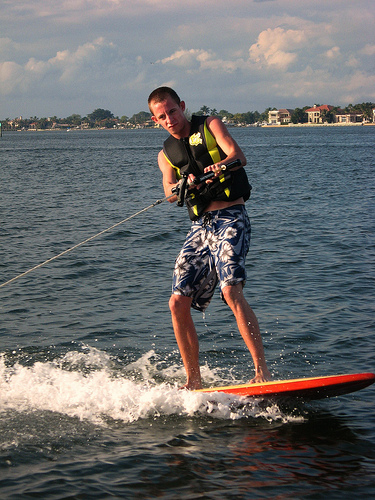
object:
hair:
[148, 86, 181, 115]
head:
[148, 86, 185, 134]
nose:
[165, 112, 173, 124]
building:
[335, 110, 365, 123]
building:
[305, 104, 341, 123]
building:
[268, 109, 293, 125]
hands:
[204, 161, 221, 183]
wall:
[268, 111, 277, 123]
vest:
[162, 114, 251, 220]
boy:
[148, 87, 272, 392]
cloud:
[0, 0, 375, 110]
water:
[268, 148, 358, 331]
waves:
[0, 346, 284, 426]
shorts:
[171, 203, 251, 312]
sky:
[0, 0, 375, 103]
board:
[191, 371, 375, 396]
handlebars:
[171, 158, 242, 193]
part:
[289, 372, 375, 399]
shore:
[0, 119, 375, 133]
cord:
[0, 193, 176, 287]